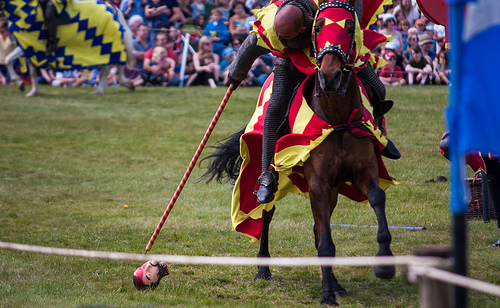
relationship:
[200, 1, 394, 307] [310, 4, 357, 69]
horse wearing mask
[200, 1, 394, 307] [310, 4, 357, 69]
horse has mask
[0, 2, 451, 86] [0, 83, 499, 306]
people in grass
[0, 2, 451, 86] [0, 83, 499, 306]
people on grass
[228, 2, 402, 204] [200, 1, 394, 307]
man riding horse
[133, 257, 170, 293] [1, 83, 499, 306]
head on ground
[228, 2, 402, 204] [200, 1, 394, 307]
man on horse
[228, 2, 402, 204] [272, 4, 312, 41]
man has head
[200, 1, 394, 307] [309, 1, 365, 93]
horse has head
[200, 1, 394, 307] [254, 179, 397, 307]
horse has legs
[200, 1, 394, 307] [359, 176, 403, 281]
horse has leg